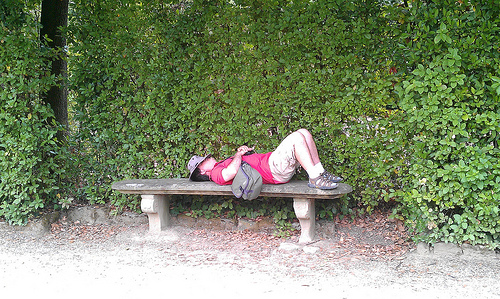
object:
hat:
[187, 153, 211, 180]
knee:
[288, 128, 313, 143]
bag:
[231, 163, 263, 200]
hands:
[238, 145, 247, 154]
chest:
[222, 154, 237, 170]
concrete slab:
[110, 179, 353, 200]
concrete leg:
[141, 195, 169, 232]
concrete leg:
[292, 198, 315, 242]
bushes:
[152, 13, 401, 220]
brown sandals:
[308, 171, 343, 189]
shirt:
[210, 152, 275, 185]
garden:
[0, 0, 499, 297]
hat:
[183, 150, 201, 176]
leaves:
[221, 201, 229, 207]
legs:
[270, 124, 319, 168]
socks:
[306, 162, 325, 178]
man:
[187, 128, 344, 189]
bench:
[110, 180, 353, 244]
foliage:
[124, 39, 196, 72]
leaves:
[52, 217, 80, 233]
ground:
[0, 225, 498, 298]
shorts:
[269, 140, 295, 182]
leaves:
[237, 232, 249, 238]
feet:
[308, 175, 335, 187]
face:
[198, 157, 214, 169]